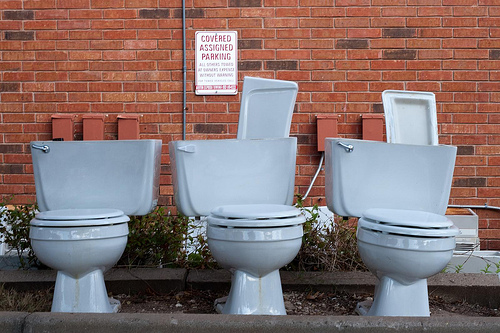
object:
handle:
[31, 140, 51, 155]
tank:
[321, 134, 462, 218]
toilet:
[167, 137, 306, 281]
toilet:
[324, 137, 462, 284]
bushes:
[135, 226, 199, 261]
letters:
[199, 32, 206, 44]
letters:
[225, 32, 232, 44]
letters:
[197, 42, 204, 52]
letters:
[201, 52, 207, 60]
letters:
[225, 52, 233, 60]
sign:
[193, 26, 237, 95]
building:
[1, 0, 157, 136]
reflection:
[234, 277, 277, 313]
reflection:
[56, 265, 105, 310]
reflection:
[392, 278, 424, 312]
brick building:
[1, 0, 498, 249]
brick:
[53, 20, 90, 30]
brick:
[101, 49, 136, 59]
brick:
[136, 26, 173, 39]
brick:
[67, 70, 100, 81]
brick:
[121, 81, 158, 93]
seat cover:
[211, 187, 299, 226]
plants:
[126, 245, 146, 257]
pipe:
[447, 200, 499, 212]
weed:
[1, 208, 26, 256]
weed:
[186, 230, 210, 263]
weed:
[325, 227, 347, 266]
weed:
[436, 239, 498, 276]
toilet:
[25, 137, 162, 314]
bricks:
[331, 23, 425, 76]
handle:
[332, 138, 351, 155]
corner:
[224, 31, 244, 55]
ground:
[313, 298, 353, 331]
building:
[294, 17, 499, 141]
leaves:
[148, 235, 176, 259]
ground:
[470, 295, 483, 305]